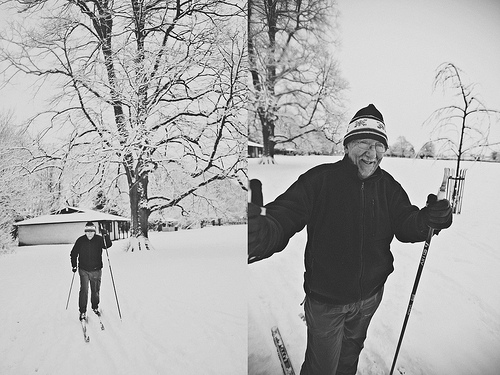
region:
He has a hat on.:
[332, 98, 407, 137]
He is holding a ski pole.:
[253, 102, 468, 369]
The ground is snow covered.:
[18, 243, 242, 368]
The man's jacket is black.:
[61, 231, 112, 268]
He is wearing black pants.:
[60, 273, 120, 323]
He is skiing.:
[34, 200, 151, 358]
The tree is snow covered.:
[8, 0, 255, 241]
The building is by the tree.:
[11, 199, 124, 241]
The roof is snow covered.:
[18, 207, 132, 249]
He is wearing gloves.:
[420, 188, 472, 235]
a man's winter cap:
[345, 105, 389, 141]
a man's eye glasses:
[353, 139, 385, 150]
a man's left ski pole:
[390, 168, 450, 374]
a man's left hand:
[422, 193, 454, 235]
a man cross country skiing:
[67, 221, 123, 339]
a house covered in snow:
[14, 206, 133, 246]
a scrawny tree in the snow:
[432, 64, 498, 212]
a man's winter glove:
[424, 193, 454, 234]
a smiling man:
[249, 103, 454, 373]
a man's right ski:
[75, 315, 96, 344]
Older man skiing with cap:
[60, 216, 135, 358]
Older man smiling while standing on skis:
[245, 97, 463, 374]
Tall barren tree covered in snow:
[2, 2, 247, 252]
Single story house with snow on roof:
[11, 200, 132, 250]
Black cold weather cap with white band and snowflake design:
[342, 102, 399, 149]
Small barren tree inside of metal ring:
[415, 54, 499, 221]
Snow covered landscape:
[125, 256, 246, 369]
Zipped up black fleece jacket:
[247, 156, 456, 311]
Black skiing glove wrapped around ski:
[421, 188, 458, 241]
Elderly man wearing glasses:
[269, 87, 421, 374]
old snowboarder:
[252, 97, 450, 372]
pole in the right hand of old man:
[390, 202, 439, 372]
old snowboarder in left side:
[70, 218, 112, 322]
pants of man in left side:
[76, 268, 99, 325]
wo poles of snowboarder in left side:
[53, 239, 120, 316]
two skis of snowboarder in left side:
[79, 305, 109, 340]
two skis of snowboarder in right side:
[265, 316, 344, 370]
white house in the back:
[15, 203, 137, 247]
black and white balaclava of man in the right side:
[337, 100, 387, 140]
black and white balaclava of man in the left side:
[81, 220, 101, 231]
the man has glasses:
[236, 118, 443, 373]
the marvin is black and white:
[346, 109, 398, 152]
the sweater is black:
[286, 174, 417, 299]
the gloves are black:
[416, 197, 458, 236]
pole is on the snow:
[384, 217, 448, 350]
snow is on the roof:
[45, 205, 125, 222]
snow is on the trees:
[80, 110, 159, 160]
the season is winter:
[8, 85, 493, 371]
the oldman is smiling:
[241, 131, 449, 373]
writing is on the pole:
[414, 247, 430, 270]